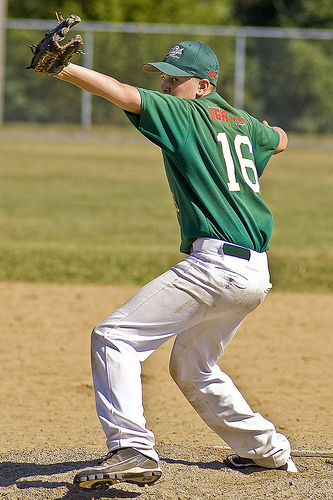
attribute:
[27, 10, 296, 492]
boy — throwing ball, person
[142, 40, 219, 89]
hat — green, red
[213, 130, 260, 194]
number — white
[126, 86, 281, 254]
shirt — green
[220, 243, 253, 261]
belt — green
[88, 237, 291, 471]
pants — white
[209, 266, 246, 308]
pocket — white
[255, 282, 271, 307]
pocket — white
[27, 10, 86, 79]
glove — brown, leather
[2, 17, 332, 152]
fence — chain link, distant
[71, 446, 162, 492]
shoe — brown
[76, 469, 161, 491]
sole — yellow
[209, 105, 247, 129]
sponsor name — red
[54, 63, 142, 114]
arm — outstretched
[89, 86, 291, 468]
uniform — green, white